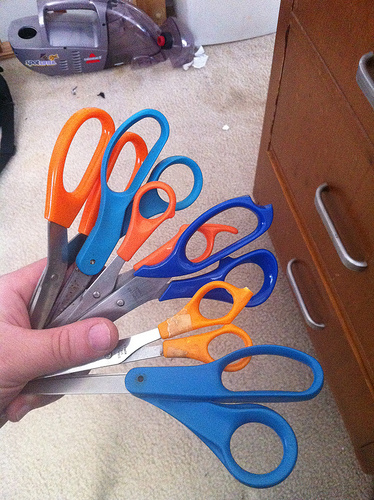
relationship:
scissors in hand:
[39, 343, 333, 474] [2, 258, 123, 411]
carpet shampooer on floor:
[12, 7, 203, 71] [5, 41, 362, 496]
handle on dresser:
[302, 173, 373, 290] [238, 9, 371, 472]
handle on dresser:
[275, 255, 338, 348] [238, 9, 371, 472]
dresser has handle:
[238, 9, 371, 472] [302, 173, 373, 290]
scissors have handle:
[18, 90, 156, 336] [45, 107, 148, 239]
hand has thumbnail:
[2, 258, 123, 411] [82, 321, 117, 355]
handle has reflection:
[302, 173, 373, 290] [322, 188, 367, 265]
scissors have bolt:
[59, 174, 294, 340] [110, 295, 128, 311]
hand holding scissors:
[2, 258, 123, 411] [18, 90, 156, 336]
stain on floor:
[201, 64, 274, 142] [5, 41, 362, 496]